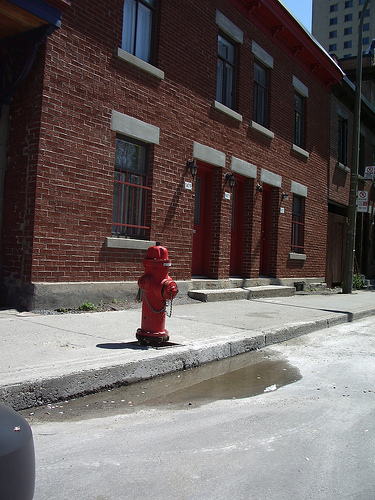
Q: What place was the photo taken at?
A: It was taken at the city.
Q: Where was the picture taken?
A: It was taken at the city.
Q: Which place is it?
A: It is a city.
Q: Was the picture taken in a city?
A: Yes, it was taken in a city.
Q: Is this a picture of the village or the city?
A: It is showing the city.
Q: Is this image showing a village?
A: No, the picture is showing a city.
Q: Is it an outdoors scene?
A: Yes, it is outdoors.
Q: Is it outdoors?
A: Yes, it is outdoors.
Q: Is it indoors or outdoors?
A: It is outdoors.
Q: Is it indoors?
A: No, it is outdoors.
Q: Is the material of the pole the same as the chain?
A: Yes, both the pole and the chain are made of metal.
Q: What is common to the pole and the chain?
A: The material, both the pole and the chain are metallic.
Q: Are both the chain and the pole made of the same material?
A: Yes, both the chain and the pole are made of metal.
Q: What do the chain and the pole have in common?
A: The material, both the chain and the pole are metallic.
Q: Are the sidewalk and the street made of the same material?
A: Yes, both the sidewalk and the street are made of concrete.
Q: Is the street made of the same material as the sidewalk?
A: Yes, both the street and the sidewalk are made of cement.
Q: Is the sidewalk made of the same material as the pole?
A: No, the sidewalk is made of concrete and the pole is made of metal.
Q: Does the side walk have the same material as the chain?
A: No, the side walk is made of cement and the chain is made of metal.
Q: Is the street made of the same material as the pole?
A: No, the street is made of concrete and the pole is made of metal.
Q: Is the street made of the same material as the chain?
A: No, the street is made of cement and the chain is made of metal.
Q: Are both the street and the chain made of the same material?
A: No, the street is made of cement and the chain is made of metal.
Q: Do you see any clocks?
A: No, there are no clocks.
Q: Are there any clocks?
A: No, there are no clocks.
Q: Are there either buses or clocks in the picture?
A: No, there are no clocks or buses.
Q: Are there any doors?
A: Yes, there is a door.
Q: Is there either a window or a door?
A: Yes, there is a door.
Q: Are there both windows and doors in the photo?
A: Yes, there are both a door and windows.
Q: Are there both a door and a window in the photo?
A: Yes, there are both a door and a window.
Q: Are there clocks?
A: No, there are no clocks.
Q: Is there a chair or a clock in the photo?
A: No, there are no clocks or chairs.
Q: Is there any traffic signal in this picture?
A: No, there are no traffic lights.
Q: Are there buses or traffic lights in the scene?
A: No, there are no traffic lights or buses.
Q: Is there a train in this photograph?
A: No, there are no trains.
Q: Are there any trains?
A: No, there are no trains.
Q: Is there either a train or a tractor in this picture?
A: No, there are no trains or tractors.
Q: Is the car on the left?
A: Yes, the car is on the left of the image.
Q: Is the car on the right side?
A: No, the car is on the left of the image.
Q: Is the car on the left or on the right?
A: The car is on the left of the image.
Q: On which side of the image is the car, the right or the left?
A: The car is on the left of the image.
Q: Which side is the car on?
A: The car is on the left of the image.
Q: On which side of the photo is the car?
A: The car is on the left of the image.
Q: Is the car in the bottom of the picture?
A: Yes, the car is in the bottom of the image.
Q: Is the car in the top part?
A: No, the car is in the bottom of the image.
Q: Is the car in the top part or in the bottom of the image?
A: The car is in the bottom of the image.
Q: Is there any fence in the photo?
A: No, there are no fences.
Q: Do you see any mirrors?
A: No, there are no mirrors.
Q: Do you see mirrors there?
A: No, there are no mirrors.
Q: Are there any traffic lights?
A: No, there are no traffic lights.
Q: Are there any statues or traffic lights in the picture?
A: No, there are no traffic lights or statues.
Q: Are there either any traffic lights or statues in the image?
A: No, there are no traffic lights or statues.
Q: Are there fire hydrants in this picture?
A: Yes, there is a fire hydrant.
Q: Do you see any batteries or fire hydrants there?
A: Yes, there is a fire hydrant.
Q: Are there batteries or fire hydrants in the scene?
A: Yes, there is a fire hydrant.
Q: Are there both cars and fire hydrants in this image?
A: Yes, there are both a fire hydrant and a car.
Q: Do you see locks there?
A: No, there are no locks.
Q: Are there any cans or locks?
A: No, there are no locks or cans.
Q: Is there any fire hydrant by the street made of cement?
A: Yes, there is a fire hydrant by the street.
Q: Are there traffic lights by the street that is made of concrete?
A: No, there is a fire hydrant by the street.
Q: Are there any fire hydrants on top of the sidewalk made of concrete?
A: Yes, there is a fire hydrant on top of the sidewalk.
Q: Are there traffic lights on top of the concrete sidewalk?
A: No, there is a fire hydrant on top of the sidewalk.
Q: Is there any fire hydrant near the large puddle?
A: Yes, there is a fire hydrant near the puddle.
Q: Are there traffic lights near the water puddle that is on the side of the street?
A: No, there is a fire hydrant near the puddle.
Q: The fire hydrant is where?
A: The fire hydrant is on the street.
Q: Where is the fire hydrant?
A: The fire hydrant is on the street.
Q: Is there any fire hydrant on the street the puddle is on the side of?
A: Yes, there is a fire hydrant on the street.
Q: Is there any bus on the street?
A: No, there is a fire hydrant on the street.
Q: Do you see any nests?
A: No, there are no nests.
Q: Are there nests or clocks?
A: No, there are no nests or clocks.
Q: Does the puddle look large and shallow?
A: Yes, the puddle is large and shallow.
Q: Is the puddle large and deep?
A: No, the puddle is large but shallow.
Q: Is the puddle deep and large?
A: No, the puddle is large but shallow.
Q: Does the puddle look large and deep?
A: No, the puddle is large but shallow.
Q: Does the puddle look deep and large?
A: No, the puddle is large but shallow.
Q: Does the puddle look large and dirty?
A: Yes, the puddle is large and dirty.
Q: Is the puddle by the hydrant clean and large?
A: No, the puddle is large but dirty.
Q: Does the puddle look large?
A: Yes, the puddle is large.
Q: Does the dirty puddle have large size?
A: Yes, the puddle is large.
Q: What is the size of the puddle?
A: The puddle is large.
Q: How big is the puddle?
A: The puddle is large.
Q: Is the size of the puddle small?
A: No, the puddle is large.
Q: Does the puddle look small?
A: No, the puddle is large.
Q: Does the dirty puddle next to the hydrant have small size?
A: No, the puddle is large.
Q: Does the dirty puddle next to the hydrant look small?
A: No, the puddle is large.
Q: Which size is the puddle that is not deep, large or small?
A: The puddle is large.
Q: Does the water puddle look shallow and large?
A: Yes, the puddle is shallow and large.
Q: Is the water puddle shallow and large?
A: Yes, the puddle is shallow and large.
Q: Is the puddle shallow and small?
A: No, the puddle is shallow but large.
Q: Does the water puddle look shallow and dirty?
A: Yes, the puddle is shallow and dirty.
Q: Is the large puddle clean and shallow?
A: No, the puddle is shallow but dirty.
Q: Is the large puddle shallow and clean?
A: No, the puddle is shallow but dirty.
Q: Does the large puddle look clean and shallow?
A: No, the puddle is shallow but dirty.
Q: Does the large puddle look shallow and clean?
A: No, the puddle is shallow but dirty.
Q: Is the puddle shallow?
A: Yes, the puddle is shallow.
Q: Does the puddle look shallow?
A: Yes, the puddle is shallow.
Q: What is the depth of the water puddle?
A: The puddle is shallow.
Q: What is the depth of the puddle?
A: The puddle is shallow.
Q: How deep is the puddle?
A: The puddle is shallow.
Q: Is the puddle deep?
A: No, the puddle is shallow.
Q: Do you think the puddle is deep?
A: No, the puddle is shallow.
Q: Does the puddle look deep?
A: No, the puddle is shallow.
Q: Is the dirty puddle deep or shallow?
A: The puddle is shallow.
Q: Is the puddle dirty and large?
A: Yes, the puddle is dirty and large.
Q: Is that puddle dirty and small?
A: No, the puddle is dirty but large.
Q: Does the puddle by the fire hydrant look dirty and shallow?
A: Yes, the puddle is dirty and shallow.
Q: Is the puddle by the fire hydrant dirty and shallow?
A: Yes, the puddle is dirty and shallow.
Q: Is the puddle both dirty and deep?
A: No, the puddle is dirty but shallow.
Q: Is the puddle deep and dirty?
A: No, the puddle is dirty but shallow.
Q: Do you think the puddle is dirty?
A: Yes, the puddle is dirty.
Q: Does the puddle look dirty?
A: Yes, the puddle is dirty.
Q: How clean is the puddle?
A: The puddle is dirty.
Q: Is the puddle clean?
A: No, the puddle is dirty.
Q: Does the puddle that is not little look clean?
A: No, the puddle is dirty.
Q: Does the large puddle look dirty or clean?
A: The puddle is dirty.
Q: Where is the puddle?
A: The puddle is in the street.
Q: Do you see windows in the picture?
A: Yes, there is a window.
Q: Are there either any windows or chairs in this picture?
A: Yes, there is a window.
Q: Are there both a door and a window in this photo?
A: Yes, there are both a window and a door.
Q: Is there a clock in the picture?
A: No, there are no clocks.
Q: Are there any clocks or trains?
A: No, there are no clocks or trains.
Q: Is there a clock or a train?
A: No, there are no clocks or trains.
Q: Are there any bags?
A: No, there are no bags.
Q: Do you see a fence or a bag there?
A: No, there are no bags or fences.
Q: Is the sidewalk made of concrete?
A: Yes, the sidewalk is made of concrete.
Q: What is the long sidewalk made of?
A: The sidewalk is made of cement.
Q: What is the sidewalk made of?
A: The sidewalk is made of concrete.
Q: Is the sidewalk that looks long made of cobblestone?
A: No, the side walk is made of concrete.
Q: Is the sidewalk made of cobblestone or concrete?
A: The sidewalk is made of concrete.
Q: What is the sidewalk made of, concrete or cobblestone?
A: The sidewalk is made of concrete.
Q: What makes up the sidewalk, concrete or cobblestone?
A: The sidewalk is made of concrete.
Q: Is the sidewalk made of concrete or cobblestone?
A: The sidewalk is made of concrete.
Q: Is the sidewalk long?
A: Yes, the sidewalk is long.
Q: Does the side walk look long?
A: Yes, the side walk is long.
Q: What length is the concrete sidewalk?
A: The sidewalk is long.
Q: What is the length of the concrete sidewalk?
A: The sidewalk is long.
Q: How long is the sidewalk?
A: The sidewalk is long.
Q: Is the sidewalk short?
A: No, the sidewalk is long.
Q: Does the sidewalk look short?
A: No, the sidewalk is long.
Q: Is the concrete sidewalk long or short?
A: The sidewalk is long.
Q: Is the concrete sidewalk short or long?
A: The sidewalk is long.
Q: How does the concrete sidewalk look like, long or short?
A: The sidewalk is long.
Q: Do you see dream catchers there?
A: No, there are no dream catchers.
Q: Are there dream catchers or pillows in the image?
A: No, there are no dream catchers or pillows.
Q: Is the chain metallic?
A: Yes, the chain is metallic.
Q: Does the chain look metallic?
A: Yes, the chain is metallic.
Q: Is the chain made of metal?
A: Yes, the chain is made of metal.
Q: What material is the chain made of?
A: The chain is made of metal.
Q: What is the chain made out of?
A: The chain is made of metal.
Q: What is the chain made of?
A: The chain is made of metal.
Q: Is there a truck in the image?
A: No, there are no trucks.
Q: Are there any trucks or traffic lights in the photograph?
A: No, there are no trucks or traffic lights.